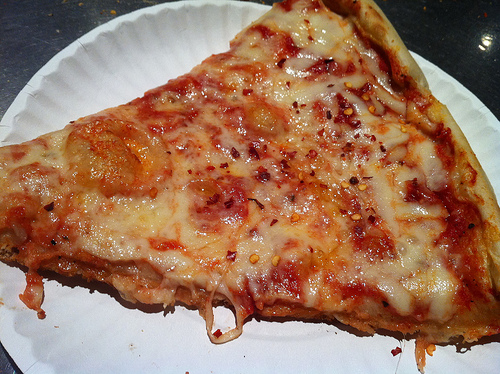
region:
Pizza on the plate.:
[0, 0, 498, 348]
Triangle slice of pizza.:
[0, 1, 499, 341]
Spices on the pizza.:
[339, 178, 369, 191]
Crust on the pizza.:
[332, 0, 496, 307]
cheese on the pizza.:
[87, 195, 201, 276]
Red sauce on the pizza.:
[442, 197, 478, 253]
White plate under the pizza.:
[0, 1, 498, 368]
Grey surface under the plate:
[2, 2, 497, 372]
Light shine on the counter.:
[471, 30, 496, 57]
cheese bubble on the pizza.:
[63, 115, 168, 195]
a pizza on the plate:
[78, 35, 462, 370]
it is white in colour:
[121, 49, 428, 351]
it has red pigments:
[108, 63, 405, 349]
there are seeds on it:
[206, 120, 380, 228]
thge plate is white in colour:
[38, 9, 318, 236]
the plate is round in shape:
[6, 2, 219, 99]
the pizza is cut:
[12, 157, 477, 369]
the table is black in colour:
[23, 6, 63, 43]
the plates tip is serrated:
[26, 0, 191, 84]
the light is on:
[453, 17, 495, 68]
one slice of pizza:
[1, 40, 484, 343]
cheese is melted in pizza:
[331, 88, 459, 318]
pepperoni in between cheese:
[70, 126, 131, 199]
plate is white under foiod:
[62, 335, 347, 370]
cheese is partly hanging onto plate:
[181, 301, 248, 342]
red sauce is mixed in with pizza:
[452, 183, 479, 303]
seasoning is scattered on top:
[190, 140, 400, 220]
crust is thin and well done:
[418, 27, 498, 210]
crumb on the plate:
[378, 342, 409, 362]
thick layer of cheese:
[93, 198, 162, 263]